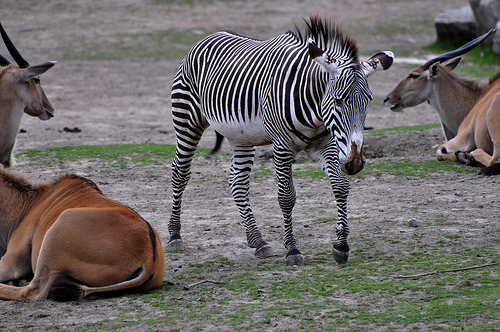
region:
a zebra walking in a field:
[163, 11, 400, 282]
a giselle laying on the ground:
[383, 35, 493, 200]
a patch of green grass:
[51, 120, 166, 179]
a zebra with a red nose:
[248, 20, 407, 210]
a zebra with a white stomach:
[180, 95, 285, 158]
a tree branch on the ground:
[396, 240, 490, 292]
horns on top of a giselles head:
[386, 16, 494, 114]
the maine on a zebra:
[258, 22, 373, 80]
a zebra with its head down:
[222, 23, 433, 208]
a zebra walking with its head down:
[148, 30, 448, 275]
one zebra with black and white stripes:
[165, 14, 394, 269]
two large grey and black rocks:
[432, 0, 499, 55]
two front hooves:
[282, 239, 352, 268]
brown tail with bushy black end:
[46, 269, 151, 305]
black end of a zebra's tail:
[207, 130, 223, 157]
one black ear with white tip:
[21, 56, 56, 76]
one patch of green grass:
[20, 135, 171, 161]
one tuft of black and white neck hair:
[283, 12, 359, 62]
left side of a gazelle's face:
[380, 58, 441, 113]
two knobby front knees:
[274, 178, 352, 210]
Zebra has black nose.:
[336, 145, 377, 215]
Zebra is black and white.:
[201, 48, 322, 146]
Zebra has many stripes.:
[197, 37, 334, 186]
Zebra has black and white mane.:
[307, 32, 406, 92]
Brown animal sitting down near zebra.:
[74, 187, 167, 322]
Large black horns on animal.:
[423, 28, 491, 91]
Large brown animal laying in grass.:
[448, 53, 483, 222]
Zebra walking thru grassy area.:
[162, 151, 365, 288]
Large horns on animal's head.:
[2, 31, 24, 61]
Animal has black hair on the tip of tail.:
[46, 272, 108, 330]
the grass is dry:
[296, 275, 457, 320]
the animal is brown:
[13, 176, 178, 298]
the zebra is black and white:
[171, 82, 357, 259]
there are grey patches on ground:
[380, 190, 476, 230]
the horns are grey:
[416, 35, 496, 66]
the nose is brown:
[336, 140, 367, 173]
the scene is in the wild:
[2, 42, 492, 328]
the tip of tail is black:
[45, 273, 86, 299]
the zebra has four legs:
[155, 46, 401, 272]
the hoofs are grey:
[280, 251, 317, 271]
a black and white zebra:
[169, 15, 395, 269]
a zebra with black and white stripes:
[167, 16, 394, 269]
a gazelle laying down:
[0, 161, 165, 308]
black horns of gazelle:
[421, 23, 498, 68]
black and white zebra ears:
[305, 42, 396, 77]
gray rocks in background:
[434, 0, 498, 47]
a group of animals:
[1, 14, 498, 300]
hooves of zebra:
[166, 238, 356, 266]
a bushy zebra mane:
[289, 13, 363, 99]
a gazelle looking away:
[0, 23, 56, 170]